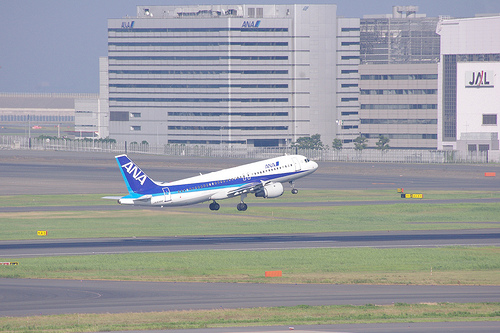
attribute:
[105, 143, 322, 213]
airplane — ready, blue, white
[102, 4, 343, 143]
building — tall, white, large, commercial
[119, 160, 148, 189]
company — name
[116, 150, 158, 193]
tail — blue, white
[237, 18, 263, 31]
name — same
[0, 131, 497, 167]
fence — white, long, tall, metal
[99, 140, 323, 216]
plane — taking off, blue, white, lifting off, jet, commercial, airborne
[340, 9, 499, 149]
buildings — extra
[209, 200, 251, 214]
wheels — out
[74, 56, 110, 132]
building — small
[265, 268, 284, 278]
symbol — orange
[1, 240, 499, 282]
grass — patch, green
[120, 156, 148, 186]
ana — word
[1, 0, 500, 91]
sky — grey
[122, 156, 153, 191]
brand — ana, plane's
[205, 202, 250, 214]
gear — landing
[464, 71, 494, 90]
letters — jxl, black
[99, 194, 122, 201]
wing — rear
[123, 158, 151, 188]
lettering — white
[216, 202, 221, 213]
wheel — black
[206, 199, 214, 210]
wheel — black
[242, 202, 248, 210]
wheel — black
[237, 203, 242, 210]
wheel — black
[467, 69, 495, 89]
sign — blue, grey, red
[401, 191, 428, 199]
object — yellow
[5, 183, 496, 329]
field — green